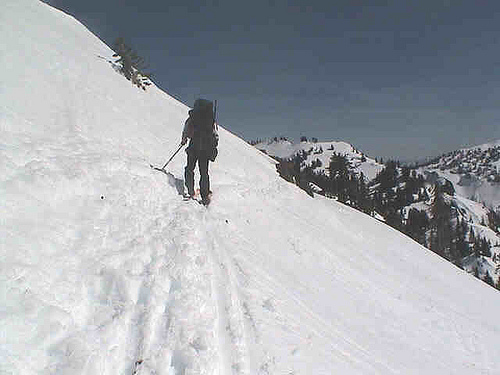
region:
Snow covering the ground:
[237, 321, 291, 373]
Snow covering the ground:
[270, 133, 315, 183]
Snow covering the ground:
[307, 131, 352, 171]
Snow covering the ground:
[345, 132, 397, 184]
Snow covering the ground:
[389, 144, 426, 193]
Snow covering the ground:
[427, 150, 479, 225]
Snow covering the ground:
[343, 228, 417, 303]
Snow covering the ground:
[425, 235, 471, 359]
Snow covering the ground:
[35, 184, 74, 253]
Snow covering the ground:
[130, 277, 262, 345]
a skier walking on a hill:
[156, 85, 233, 218]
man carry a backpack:
[160, 83, 230, 213]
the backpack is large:
[179, 92, 220, 162]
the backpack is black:
[181, 92, 221, 159]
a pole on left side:
[152, 135, 187, 172]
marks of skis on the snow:
[92, 186, 272, 367]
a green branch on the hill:
[101, 27, 152, 97]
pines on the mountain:
[260, 110, 497, 285]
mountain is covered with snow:
[236, 102, 496, 279]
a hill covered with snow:
[5, 0, 485, 370]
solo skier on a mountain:
[161, 82, 227, 218]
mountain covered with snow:
[280, 110, 456, 220]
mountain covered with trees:
[302, 120, 453, 230]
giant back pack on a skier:
[187, 95, 214, 156]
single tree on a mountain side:
[107, 21, 157, 98]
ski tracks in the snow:
[110, 200, 267, 374]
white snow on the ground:
[276, 254, 355, 320]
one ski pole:
[153, 131, 186, 173]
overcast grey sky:
[247, 36, 317, 77]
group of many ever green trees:
[285, 133, 457, 258]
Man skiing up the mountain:
[156, 93, 247, 203]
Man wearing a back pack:
[173, 95, 238, 170]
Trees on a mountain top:
[304, 107, 448, 233]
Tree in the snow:
[109, 31, 150, 109]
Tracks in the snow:
[105, 187, 329, 337]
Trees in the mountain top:
[351, 158, 450, 253]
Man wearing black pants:
[171, 143, 211, 190]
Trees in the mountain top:
[306, 115, 466, 233]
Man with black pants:
[169, 127, 239, 198]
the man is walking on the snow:
[125, 85, 240, 254]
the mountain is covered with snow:
[249, 100, 400, 214]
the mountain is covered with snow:
[316, 115, 496, 212]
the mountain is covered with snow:
[292, 119, 439, 269]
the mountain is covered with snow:
[359, 100, 490, 308]